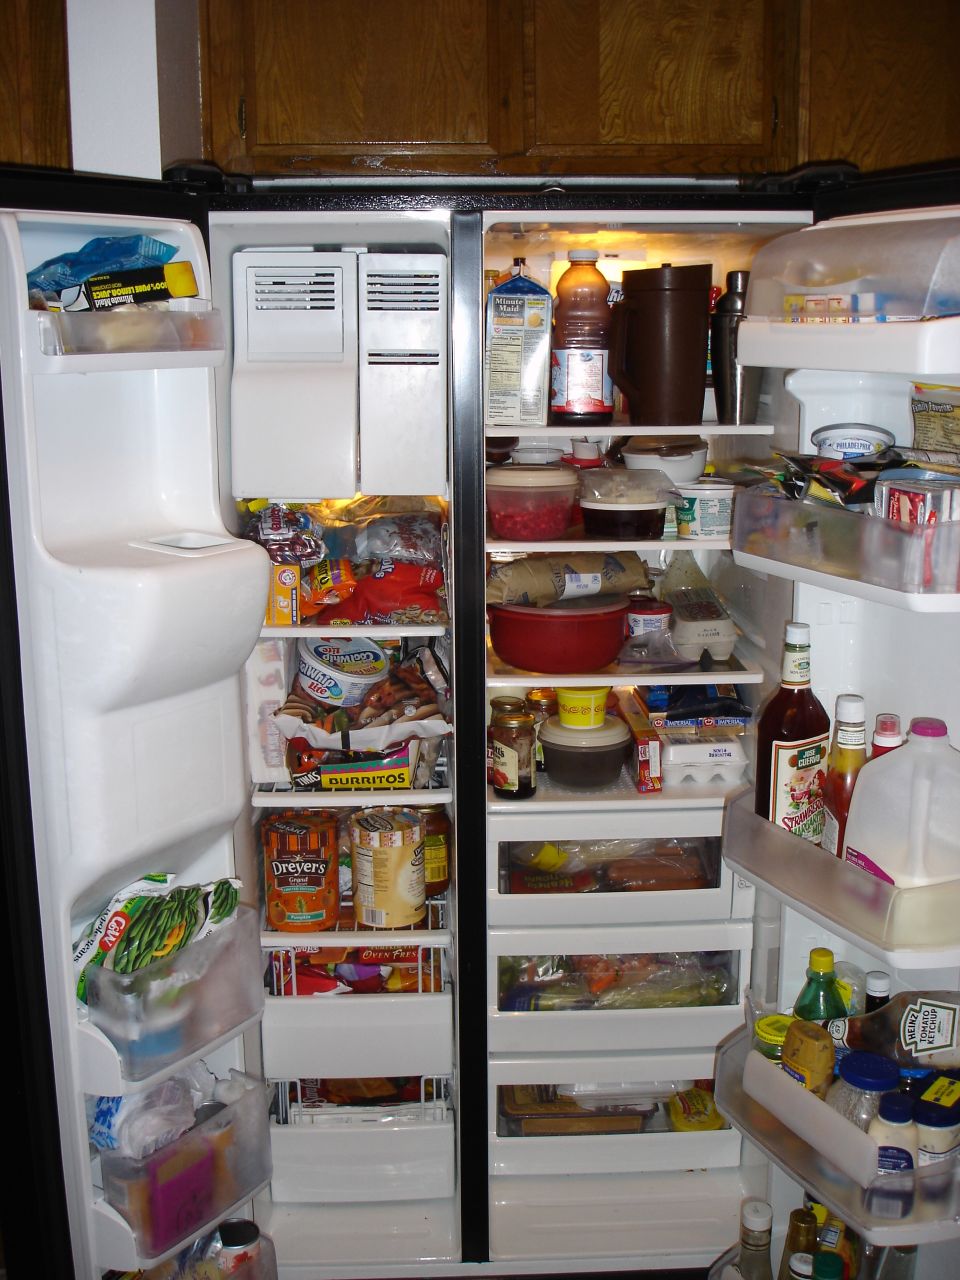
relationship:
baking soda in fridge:
[263, 561, 304, 633] [1, 146, 956, 1277]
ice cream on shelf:
[256, 805, 341, 938] [256, 909, 458, 961]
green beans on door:
[58, 865, 254, 1021] [4, 168, 267, 1270]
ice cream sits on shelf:
[340, 802, 438, 935] [246, 906, 451, 964]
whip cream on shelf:
[290, 630, 388, 720] [242, 769, 457, 825]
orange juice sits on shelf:
[486, 252, 557, 431] [486, 399, 779, 449]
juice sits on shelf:
[548, 233, 622, 423] [473, 406, 784, 454]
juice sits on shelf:
[611, 252, 712, 433] [480, 417, 789, 441]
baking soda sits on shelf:
[266, 565, 301, 626] [249, 617, 461, 643]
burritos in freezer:
[268, 717, 454, 806] [6, 189, 470, 1277]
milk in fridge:
[842, 713, 958, 948] [1, 146, 956, 1277]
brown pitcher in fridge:
[603, 256, 708, 435] [1, 146, 956, 1277]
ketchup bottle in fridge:
[822, 688, 871, 864] [1, 146, 956, 1277]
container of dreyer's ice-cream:
[259, 813, 337, 929] [254, 813, 344, 936]